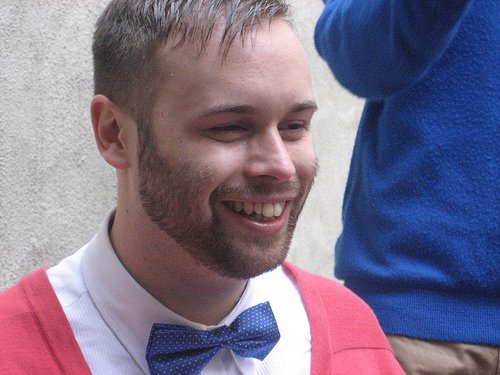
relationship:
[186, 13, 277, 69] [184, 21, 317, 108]
hair on top of forehead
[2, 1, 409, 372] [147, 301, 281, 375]
man has bow tie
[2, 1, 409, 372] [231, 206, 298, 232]
man has lip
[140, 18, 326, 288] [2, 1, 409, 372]
face on man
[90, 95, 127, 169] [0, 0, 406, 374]
ear on man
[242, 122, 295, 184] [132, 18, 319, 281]
nose on face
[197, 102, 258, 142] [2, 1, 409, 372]
eye on man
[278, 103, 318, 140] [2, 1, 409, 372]
eye belonging to man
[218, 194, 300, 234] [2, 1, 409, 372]
mouth belonging to man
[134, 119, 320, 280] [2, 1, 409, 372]
beard belonging to man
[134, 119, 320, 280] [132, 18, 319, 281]
beard growing on face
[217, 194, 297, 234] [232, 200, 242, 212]
smile exposing tooth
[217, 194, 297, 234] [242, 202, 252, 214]
smile exposing tooth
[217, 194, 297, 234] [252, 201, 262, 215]
smile exposing tooth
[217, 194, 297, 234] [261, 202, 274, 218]
smile exposing teeth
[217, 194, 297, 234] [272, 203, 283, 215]
smile exposing tooth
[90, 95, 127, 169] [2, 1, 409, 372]
ear belonging to man